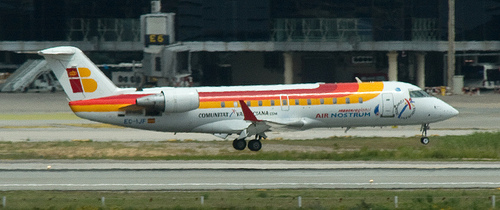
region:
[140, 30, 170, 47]
yellow light letters in the distance.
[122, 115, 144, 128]
EC-UF beneath engine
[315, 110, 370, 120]
AIR NOSTRUM, air in red, nostrum in blue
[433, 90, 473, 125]
airplane has especially pointy nose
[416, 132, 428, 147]
tiny wheel beneath airplane's pointy nose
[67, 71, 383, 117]
stripe of yellow orange paint surrounds multiple windows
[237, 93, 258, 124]
bright red fin on airplane's side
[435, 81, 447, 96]
little yellow trash can in distance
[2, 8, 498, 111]
most of the items in this airport are made of concrete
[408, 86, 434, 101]
thin wraparound window so the pilot's can look at the world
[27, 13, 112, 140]
Tail section of the airplane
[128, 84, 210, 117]
Jet engine of the airplane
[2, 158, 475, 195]
Airport runway for planes to land on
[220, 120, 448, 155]
Landing gear for the airplane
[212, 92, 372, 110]
Passenger windows on this plane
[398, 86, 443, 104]
Cockpit window on the plane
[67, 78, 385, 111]
Red, orange and yellow stripes on the plane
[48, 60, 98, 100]
B Symbol on tail of this airplane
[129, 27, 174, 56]
Airport Sign indicating E6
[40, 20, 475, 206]
Small airplane landing on runway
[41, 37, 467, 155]
A plane on the runway to land.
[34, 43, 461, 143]
The plane is red, yellow and white.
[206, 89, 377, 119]
The plane has a lot of windows.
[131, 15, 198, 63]
The letter on the crane behind the plane is E6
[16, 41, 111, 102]
The tail of the plane has a letter B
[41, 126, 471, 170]
The grass is between the runway on each side.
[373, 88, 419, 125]
The front door of the plane.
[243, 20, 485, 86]
The ramps of the airport of empty.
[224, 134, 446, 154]
The wheels of the plane are down.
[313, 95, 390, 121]
The writing on the plane is red and blue.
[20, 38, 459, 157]
a airplane taking off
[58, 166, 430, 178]
the landing in which the plane took off from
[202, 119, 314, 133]
a wing of a plane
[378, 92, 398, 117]
a side door of a plane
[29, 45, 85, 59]
a back wing of a plane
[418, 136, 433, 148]
a front wheel of a plane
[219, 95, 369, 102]
side windows of a plane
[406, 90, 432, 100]
front windows of a plane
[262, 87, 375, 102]
a dark red, red and orange color scheme on a side of the plane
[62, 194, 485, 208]
a fence near the airplane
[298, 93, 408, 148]
Air Nostrum logo on plane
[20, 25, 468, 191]
plane taking off from runway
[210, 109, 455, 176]
landing gear of commercial aircraft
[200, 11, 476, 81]
airport behind the runway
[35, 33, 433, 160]
plane with red, orange, and yellow stripes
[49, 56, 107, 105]
logo for Air Nostrum airlines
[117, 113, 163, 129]
plane number with Spanish flag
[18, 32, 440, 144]
a plane that originates from Spain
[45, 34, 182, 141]
tail and engine of plane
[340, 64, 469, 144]
nose of Air Nostrum plane